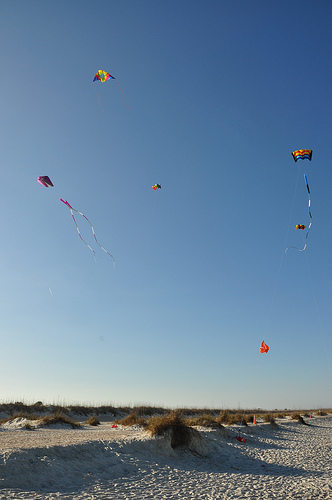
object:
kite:
[152, 183, 161, 190]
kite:
[93, 69, 130, 113]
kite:
[38, 176, 116, 266]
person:
[237, 429, 242, 438]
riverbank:
[0, 415, 332, 499]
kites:
[296, 224, 306, 230]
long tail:
[285, 174, 312, 255]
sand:
[0, 411, 331, 498]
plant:
[0, 400, 332, 436]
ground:
[0, 402, 331, 500]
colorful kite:
[260, 340, 269, 353]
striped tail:
[59, 198, 115, 266]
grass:
[0, 400, 332, 436]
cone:
[253, 414, 256, 424]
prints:
[230, 462, 270, 471]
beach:
[0, 410, 331, 499]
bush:
[0, 400, 332, 435]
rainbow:
[93, 70, 112, 82]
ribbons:
[285, 174, 313, 254]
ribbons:
[59, 197, 114, 261]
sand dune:
[0, 400, 332, 500]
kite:
[285, 149, 312, 257]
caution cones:
[253, 414, 311, 424]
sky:
[1, 1, 332, 410]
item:
[253, 414, 257, 424]